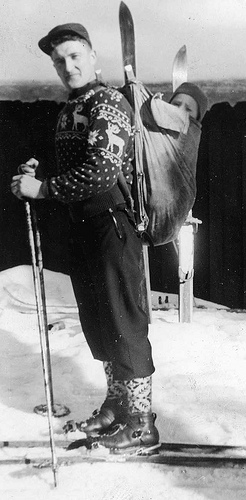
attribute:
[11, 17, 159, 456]
man — skiing, tall, looking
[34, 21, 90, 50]
hat — dark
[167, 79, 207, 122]
baby — carried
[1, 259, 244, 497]
snow — white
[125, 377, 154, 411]
sock — thermal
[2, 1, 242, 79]
sky — sunny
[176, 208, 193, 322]
object — metal